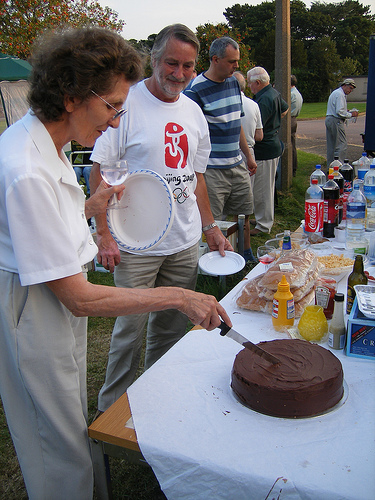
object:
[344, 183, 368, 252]
bottle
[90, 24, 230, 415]
man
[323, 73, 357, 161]
man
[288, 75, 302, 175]
man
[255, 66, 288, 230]
man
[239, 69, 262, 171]
man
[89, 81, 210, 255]
white t-shirt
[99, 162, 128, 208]
glass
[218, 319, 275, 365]
knife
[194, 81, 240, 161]
stripes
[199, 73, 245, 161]
shirt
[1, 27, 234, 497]
woman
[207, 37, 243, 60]
hair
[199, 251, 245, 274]
plate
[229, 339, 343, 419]
chocolate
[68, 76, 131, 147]
face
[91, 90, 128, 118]
glasses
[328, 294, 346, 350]
bottle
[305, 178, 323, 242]
bottle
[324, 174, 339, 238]
bottle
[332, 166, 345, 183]
bottle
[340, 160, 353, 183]
bottle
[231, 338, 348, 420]
cake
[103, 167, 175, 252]
plate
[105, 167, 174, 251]
trim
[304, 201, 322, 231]
coca cola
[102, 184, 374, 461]
table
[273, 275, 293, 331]
mustard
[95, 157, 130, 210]
hand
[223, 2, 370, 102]
trees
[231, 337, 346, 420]
frosting